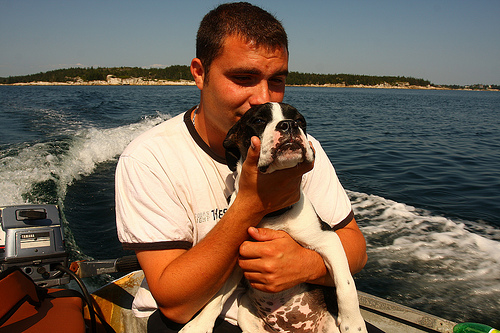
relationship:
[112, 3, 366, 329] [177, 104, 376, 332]
man holding puppy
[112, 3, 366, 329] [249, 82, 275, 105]
man man holding a puppy nose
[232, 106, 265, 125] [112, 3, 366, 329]
mouth on man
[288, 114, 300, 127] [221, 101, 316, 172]
eye on face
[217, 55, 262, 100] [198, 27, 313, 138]
eye on face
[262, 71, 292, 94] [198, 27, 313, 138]
eye on face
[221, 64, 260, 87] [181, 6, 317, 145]
eye on face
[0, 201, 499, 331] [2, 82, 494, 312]
boat on water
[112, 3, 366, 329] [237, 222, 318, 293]
man has hand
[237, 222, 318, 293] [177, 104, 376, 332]
hand on puppy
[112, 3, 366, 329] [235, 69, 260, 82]
man has eye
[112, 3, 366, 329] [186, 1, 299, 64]
man has hair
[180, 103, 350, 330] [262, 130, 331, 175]
dog has mouth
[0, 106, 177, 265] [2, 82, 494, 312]
wave in water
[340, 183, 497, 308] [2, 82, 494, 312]
wave in water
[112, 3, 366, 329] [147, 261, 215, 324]
man has elbow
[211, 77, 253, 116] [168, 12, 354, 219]
cheek of a man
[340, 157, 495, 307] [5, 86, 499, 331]
wave in water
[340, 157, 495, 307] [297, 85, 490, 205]
wave in water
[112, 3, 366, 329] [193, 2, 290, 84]
man has hair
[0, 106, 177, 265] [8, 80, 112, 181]
wave in water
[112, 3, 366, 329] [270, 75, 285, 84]
man has eye